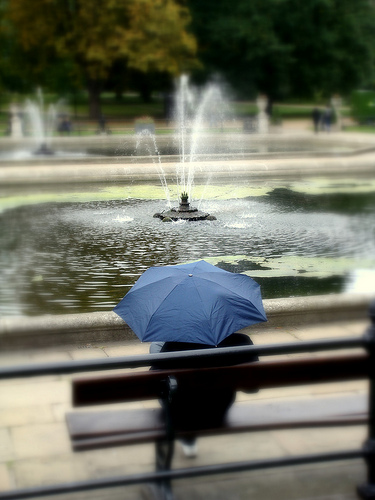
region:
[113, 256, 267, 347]
dark blue umbrella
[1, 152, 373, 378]
large concrete water fountain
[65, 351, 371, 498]
dark wood and metal bench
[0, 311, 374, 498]
black wrought iron railing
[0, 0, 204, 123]
tree with light green leaves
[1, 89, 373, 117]
field of green grass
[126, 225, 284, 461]
this is a person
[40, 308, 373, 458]
this is a bench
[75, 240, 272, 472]
person sitting on a bench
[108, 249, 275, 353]
this is an umbrella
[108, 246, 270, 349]
the umbrella is blue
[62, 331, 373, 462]
the bench is brown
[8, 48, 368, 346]
a center water fountain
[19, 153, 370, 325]
the water is green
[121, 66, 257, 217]
an arc of water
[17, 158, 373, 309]
ripples on the water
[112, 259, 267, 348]
A blue opened umbrella.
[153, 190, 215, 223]
A black fountain in the water.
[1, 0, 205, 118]
A light colored tree that stands out past the water.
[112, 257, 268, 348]
Opened blue umbrella.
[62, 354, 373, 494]
A brown wood and metal bench.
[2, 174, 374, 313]
A brown pond with green scum on top.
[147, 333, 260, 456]
A person with white shoes on sitting under an umbrella.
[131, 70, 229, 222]
Water coming out of a black fountain in the water.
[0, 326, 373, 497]
A concrete square block walkway around the bench.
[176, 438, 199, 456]
A man's white right shoe.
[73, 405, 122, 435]
the bench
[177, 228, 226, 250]
the water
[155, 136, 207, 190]
water in the air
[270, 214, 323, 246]
water in the pond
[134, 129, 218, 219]
a fountain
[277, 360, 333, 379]
the back of the bench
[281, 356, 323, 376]
the bench is brown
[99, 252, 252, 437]
This person has a blue umberella.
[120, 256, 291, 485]
This person is sitting on a bench.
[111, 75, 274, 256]
This is a water fountain.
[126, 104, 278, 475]
This person is sitting in front of a water fountain.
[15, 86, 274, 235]
There's more than 1 water fountain here.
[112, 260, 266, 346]
umbrella is over mans head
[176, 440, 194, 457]
shoes is white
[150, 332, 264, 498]
person is sitting on the bench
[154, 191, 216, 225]
fountain is spraying water